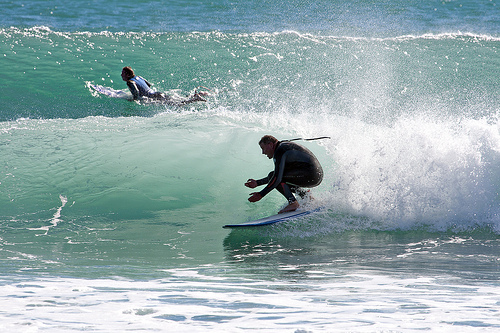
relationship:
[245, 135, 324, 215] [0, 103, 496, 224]
man riding wave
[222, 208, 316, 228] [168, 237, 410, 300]
surfboard on water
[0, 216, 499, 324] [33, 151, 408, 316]
ripples on water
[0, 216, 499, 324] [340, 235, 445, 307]
ripples in water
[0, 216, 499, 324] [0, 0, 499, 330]
ripples in water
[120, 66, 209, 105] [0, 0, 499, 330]
man in water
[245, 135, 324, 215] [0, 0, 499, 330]
man in water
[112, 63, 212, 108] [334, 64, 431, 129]
man in water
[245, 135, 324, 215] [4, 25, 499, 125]
man prepares to take a wave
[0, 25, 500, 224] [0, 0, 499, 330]
wave in water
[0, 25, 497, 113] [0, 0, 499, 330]
wave in water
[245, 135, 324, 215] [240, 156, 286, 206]
man extending h arms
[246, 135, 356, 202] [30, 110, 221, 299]
man surfing on water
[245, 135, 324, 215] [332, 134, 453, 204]
man riding wave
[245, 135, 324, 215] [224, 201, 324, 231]
man on a surfboard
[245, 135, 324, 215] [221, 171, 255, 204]
man extending hands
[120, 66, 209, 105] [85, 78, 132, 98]
man lying on surfboard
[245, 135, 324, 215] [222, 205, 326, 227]
man kneeling on board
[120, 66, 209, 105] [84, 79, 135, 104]
man on board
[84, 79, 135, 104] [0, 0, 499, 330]
board in water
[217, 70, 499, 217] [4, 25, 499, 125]
water spraying from wave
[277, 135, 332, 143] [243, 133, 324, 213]
rope tied to surfer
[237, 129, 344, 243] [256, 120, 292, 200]
wet suit on surfer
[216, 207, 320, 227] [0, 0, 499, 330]
surfboard in water